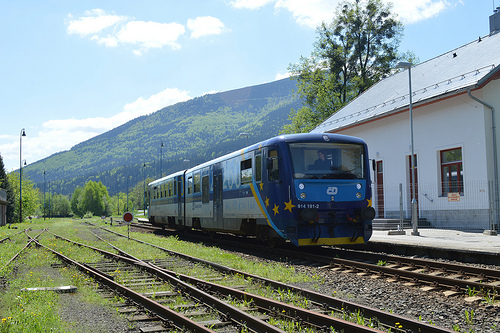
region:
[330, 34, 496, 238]
A small white building.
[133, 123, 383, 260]
A train that is mostly blue.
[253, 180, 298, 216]
Four yellow stars painted on engine.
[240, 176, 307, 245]
A yellow stripe on engine.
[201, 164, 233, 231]
Door on the engine.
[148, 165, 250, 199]
Passenger windows on the train.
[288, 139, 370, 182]
Windshield of a train.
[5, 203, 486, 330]
Grass growing up in the train tracks.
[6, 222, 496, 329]
Four sets of tracks.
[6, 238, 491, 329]
Cross ties on all the tracks.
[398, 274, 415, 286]
cross tie on the track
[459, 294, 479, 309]
cross tie on the track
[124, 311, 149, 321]
cross tie on the track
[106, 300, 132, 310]
cross tie on the track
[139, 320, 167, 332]
cross tie on the track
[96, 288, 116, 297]
cross tie on the track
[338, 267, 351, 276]
cross tie on the track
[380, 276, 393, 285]
cross tie on the track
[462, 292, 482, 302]
cross tie on the track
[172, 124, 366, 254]
A blue train car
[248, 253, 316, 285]
Green grass on the truck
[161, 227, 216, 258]
Green grass on the truck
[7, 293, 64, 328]
Green grass on the truck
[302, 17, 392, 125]
A tall green tree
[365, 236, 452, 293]
A metalic railway line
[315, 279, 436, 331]
A metalic railway line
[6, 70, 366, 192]
Green mountain in the background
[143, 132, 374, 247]
A blue train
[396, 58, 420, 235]
A gray street light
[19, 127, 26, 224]
A tall street light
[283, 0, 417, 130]
A tree with green leaves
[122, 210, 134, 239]
A red circular sign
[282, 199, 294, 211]
A yellow start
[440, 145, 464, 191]
A window with red frame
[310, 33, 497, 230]
A white building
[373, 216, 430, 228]
Steps in front of a building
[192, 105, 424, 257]
the front of a train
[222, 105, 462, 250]
a train on a track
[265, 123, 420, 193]
the windshield on a train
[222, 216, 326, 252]
the wheel on a train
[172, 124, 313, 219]
the side window on a train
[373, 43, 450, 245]
a pole near a train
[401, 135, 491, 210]
a window on a house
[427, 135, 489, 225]
a window near a train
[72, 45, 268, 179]
a mountain in the background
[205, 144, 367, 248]
a big blue train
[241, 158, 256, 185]
A window on a vehicle.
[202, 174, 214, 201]
A window on a vehicle.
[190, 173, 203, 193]
A window on a vehicle.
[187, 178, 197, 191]
A window on a vehicle.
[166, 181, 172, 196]
A window on a vehicle.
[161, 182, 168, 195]
A window on a vehicle.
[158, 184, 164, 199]
A window on a vehicle.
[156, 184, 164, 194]
A window on a vehicle.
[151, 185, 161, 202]
A window on a vehicle.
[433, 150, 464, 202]
A window on a building.